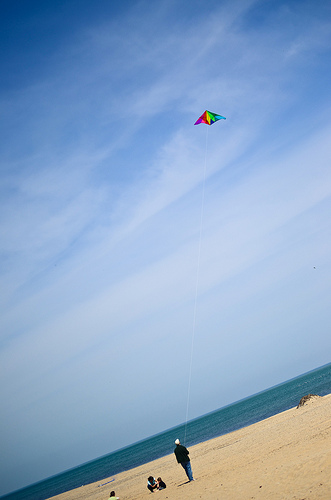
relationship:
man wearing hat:
[172, 436, 196, 479] [173, 437, 186, 452]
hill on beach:
[293, 391, 325, 408] [43, 392, 330, 497]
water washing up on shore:
[0, 362, 328, 498] [31, 381, 329, 499]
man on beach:
[174, 438, 195, 481] [143, 400, 328, 495]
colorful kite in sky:
[193, 109, 226, 126] [12, 22, 315, 356]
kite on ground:
[105, 486, 119, 498] [119, 487, 153, 498]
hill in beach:
[297, 393, 325, 410] [189, 366, 326, 498]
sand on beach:
[203, 437, 326, 495] [23, 401, 326, 499]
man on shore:
[174, 438, 195, 481] [217, 402, 325, 428]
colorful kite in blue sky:
[193, 109, 226, 126] [2, 1, 329, 498]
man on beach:
[174, 438, 195, 481] [255, 444, 301, 479]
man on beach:
[174, 438, 195, 481] [99, 353, 329, 488]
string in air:
[190, 154, 211, 291] [4, 45, 320, 460]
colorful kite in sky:
[193, 109, 226, 126] [39, 87, 173, 332]